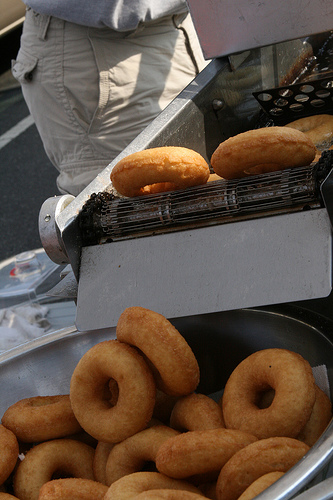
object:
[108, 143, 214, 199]
donut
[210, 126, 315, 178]
donut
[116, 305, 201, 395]
donut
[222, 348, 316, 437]
donut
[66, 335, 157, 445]
donut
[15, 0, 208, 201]
fryer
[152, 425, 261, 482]
donut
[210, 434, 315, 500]
donut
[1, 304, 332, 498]
bowl